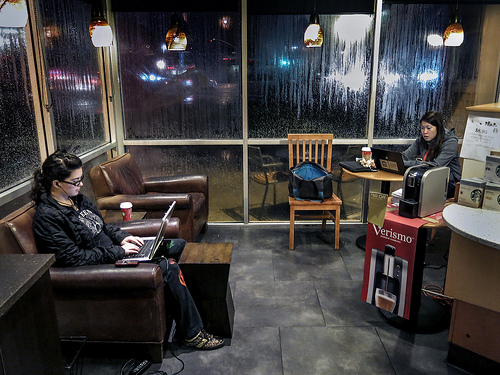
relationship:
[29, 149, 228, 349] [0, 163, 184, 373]
woman sitting on chair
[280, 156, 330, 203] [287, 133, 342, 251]
purse sitting on chair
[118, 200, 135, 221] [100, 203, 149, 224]
cup sitting on arm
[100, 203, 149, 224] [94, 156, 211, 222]
arm of chair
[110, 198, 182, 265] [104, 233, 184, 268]
laptop in lap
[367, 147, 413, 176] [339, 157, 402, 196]
laptop computer on table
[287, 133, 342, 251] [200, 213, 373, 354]
chair on floor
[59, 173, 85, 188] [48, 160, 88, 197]
glasses on face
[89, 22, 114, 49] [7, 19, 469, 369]
lights hanging in room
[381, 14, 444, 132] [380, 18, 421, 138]
glass covered with rain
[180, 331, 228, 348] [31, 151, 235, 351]
shoes on girl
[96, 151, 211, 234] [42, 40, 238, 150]
chair near window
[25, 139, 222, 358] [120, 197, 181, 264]
woman using laptop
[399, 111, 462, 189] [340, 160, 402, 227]
woman seated at table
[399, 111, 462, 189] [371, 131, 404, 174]
woman using laptop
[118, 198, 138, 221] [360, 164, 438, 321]
cup of coffee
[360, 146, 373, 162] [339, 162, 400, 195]
coffee cup on table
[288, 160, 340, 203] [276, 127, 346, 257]
bag on chair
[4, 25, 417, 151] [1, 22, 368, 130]
rain seen outside window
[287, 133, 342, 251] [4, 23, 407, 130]
chair against window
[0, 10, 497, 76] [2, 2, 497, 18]
lights hanging from ceiling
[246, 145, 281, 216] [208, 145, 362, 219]
chair on patio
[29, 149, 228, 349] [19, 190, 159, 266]
woman wearing black jacket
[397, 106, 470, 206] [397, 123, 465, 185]
woman wearing grey jacket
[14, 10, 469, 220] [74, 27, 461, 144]
glass windows with rain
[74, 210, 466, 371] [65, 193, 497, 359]
grey tile on study floor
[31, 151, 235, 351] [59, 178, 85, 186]
girl wearing glasses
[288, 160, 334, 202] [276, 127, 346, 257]
bag on chair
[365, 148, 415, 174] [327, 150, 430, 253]
laptop computer on table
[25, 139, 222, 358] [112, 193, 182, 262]
woman sitting down with laptop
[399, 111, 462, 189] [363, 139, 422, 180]
woman sitting down with laptop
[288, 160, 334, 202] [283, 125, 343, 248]
bag on chair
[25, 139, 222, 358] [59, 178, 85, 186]
woman wearing glasses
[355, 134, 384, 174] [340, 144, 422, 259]
coffee cup on table